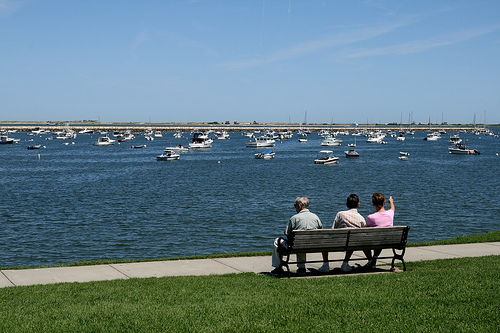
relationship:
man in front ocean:
[268, 191, 329, 279] [0, 123, 496, 261]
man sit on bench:
[268, 191, 329, 279] [278, 223, 415, 276]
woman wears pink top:
[363, 186, 399, 272] [364, 206, 398, 230]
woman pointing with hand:
[363, 186, 399, 272] [386, 192, 397, 205]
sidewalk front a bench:
[73, 242, 500, 274] [278, 223, 415, 276]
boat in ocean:
[26, 144, 42, 149] [1, 123, 499, 193]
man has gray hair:
[268, 191, 329, 279] [292, 192, 314, 212]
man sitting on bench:
[268, 191, 329, 279] [278, 223, 415, 276]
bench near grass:
[278, 223, 415, 276] [6, 267, 498, 332]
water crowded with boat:
[1, 123, 499, 193] [26, 144, 42, 149]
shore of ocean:
[8, 248, 497, 332] [1, 123, 499, 193]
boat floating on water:
[244, 135, 279, 149] [1, 123, 499, 193]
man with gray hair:
[268, 191, 329, 279] [292, 192, 314, 212]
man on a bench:
[268, 191, 329, 279] [278, 223, 415, 276]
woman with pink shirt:
[363, 186, 399, 272] [364, 206, 398, 230]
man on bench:
[268, 191, 329, 279] [278, 223, 415, 276]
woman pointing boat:
[363, 186, 399, 272] [26, 144, 42, 149]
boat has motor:
[93, 134, 119, 146] [94, 138, 101, 144]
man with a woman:
[324, 190, 370, 275] [363, 186, 399, 272]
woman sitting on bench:
[363, 186, 399, 272] [278, 223, 415, 276]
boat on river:
[26, 144, 42, 149] [1, 123, 499, 193]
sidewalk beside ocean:
[73, 242, 500, 274] [0, 123, 496, 261]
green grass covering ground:
[6, 267, 498, 332] [8, 248, 497, 332]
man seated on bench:
[268, 191, 329, 279] [278, 223, 415, 276]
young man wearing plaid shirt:
[324, 190, 370, 275] [330, 206, 369, 229]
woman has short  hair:
[363, 186, 399, 272] [369, 187, 389, 211]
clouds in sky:
[2, 3, 495, 122] [2, 3, 495, 122]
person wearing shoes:
[324, 190, 370, 275] [264, 255, 411, 281]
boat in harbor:
[26, 144, 42, 149] [0, 118, 483, 276]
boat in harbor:
[26, 144, 42, 149] [0, 121, 477, 134]